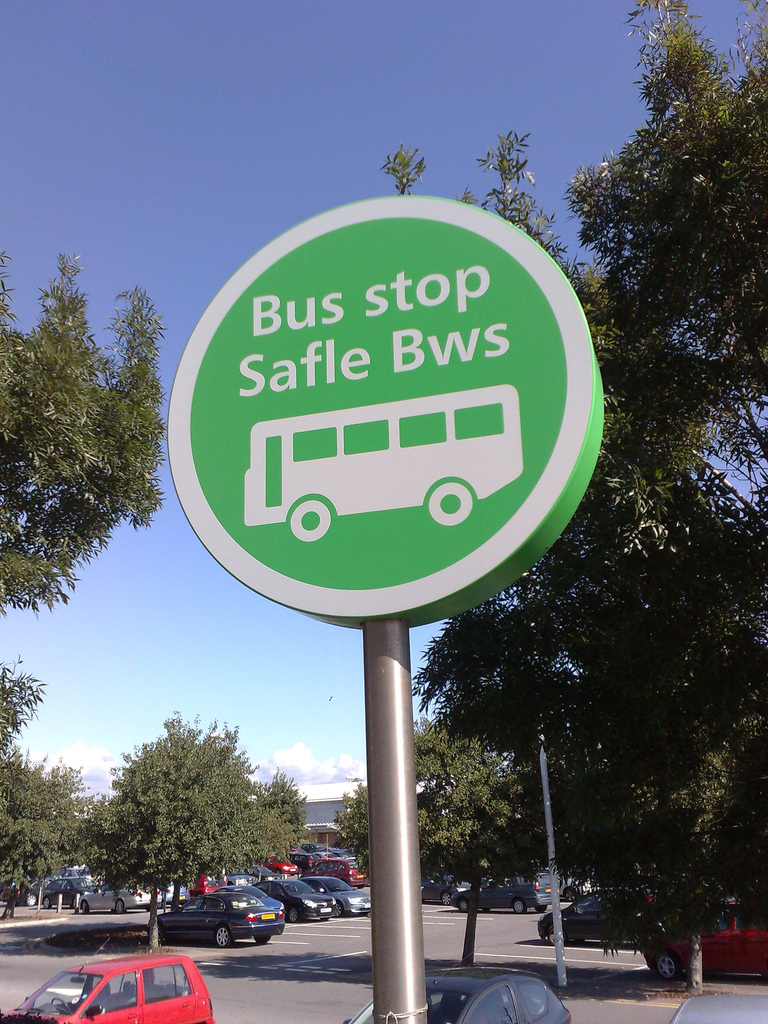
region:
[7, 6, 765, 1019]
a scene outside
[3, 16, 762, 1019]
a scene during the day time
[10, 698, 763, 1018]
a parking lot filled with cars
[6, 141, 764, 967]
some trees in the area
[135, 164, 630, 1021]
a green bus sign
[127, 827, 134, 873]
a piece of the image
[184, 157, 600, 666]
green and white bus stop sign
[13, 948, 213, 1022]
small red parked car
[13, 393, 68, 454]
green leaves on brown tree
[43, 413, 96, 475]
green leaves on brown tree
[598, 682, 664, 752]
green leaves on brown tree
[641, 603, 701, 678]
green leaves on brown tree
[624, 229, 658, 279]
green leaves on brown tree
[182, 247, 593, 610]
Green sign is round.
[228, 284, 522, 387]
White lettering on green sign.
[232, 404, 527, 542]
Picture of white bus on sign.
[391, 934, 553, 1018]
Black car parked in lot.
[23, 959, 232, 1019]
Red car parked in lot.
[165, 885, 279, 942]
Dark car parked under tree.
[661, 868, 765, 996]
Red car parked in lot.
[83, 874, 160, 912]
White car parked in lot.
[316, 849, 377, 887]
Small red car parked in lot.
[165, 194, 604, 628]
the sign is shaped like a circle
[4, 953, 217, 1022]
the car is red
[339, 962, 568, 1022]
the car is black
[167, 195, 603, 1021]
the sign on the silver pole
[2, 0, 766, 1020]
the tall green trees in the parking lot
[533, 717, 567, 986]
the pole is white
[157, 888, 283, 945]
the car is dark blue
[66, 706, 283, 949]
the tree is next to the parked blue car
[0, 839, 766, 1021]
the multiple cars parked in the parking lot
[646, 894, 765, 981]
the car is red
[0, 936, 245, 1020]
Red car is parked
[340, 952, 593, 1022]
Black car is parked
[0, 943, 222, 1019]
Red car parked in a lot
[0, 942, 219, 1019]
Red car is parked in a lot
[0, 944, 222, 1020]
Red car parked in a parking lot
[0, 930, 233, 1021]
Red car is parked in a parking lot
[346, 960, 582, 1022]
Black car in a parking lot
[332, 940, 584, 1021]
Black car is in a parking lot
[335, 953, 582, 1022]
Black car parked in a parking lot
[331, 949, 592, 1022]
Black car is parked in a parking lot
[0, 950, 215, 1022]
the car is red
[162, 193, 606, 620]
green and white sign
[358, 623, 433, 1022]
the pole is gray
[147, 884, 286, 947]
the car is parked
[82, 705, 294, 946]
tree is next to the car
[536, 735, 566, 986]
the pole is white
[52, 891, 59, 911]
small post in the parking lot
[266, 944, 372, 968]
white line is on the pavement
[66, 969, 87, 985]
rearview mirror is in the car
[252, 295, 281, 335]
sign has a letter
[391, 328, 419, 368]
sign has a letter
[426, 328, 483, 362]
sign has a letter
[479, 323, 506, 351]
sign has a letter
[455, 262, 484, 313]
sign has a letter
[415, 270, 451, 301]
sign has a letter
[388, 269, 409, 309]
sign has a letter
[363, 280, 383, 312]
sign has a letter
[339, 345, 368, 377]
sign has a letter